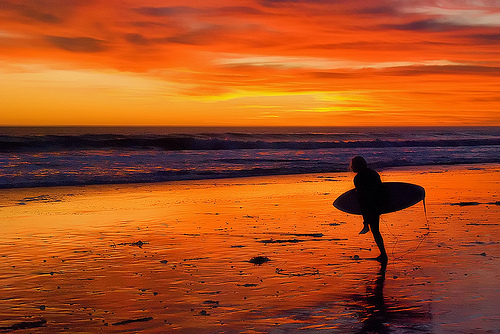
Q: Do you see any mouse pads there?
A: No, there are no mouse pads.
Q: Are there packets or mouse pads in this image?
A: No, there are no mouse pads or packets.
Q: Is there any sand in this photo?
A: Yes, there is sand.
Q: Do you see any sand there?
A: Yes, there is sand.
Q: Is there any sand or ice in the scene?
A: Yes, there is sand.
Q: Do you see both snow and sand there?
A: No, there is sand but no snow.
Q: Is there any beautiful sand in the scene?
A: Yes, there is beautiful sand.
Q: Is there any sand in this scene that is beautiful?
A: Yes, there is sand that is beautiful.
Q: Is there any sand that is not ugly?
A: Yes, there is beautiful sand.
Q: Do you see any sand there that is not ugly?
A: Yes, there is beautiful sand.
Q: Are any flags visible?
A: No, there are no flags.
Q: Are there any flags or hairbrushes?
A: No, there are no flags or hairbrushes.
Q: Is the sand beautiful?
A: Yes, the sand is beautiful.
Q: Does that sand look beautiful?
A: Yes, the sand is beautiful.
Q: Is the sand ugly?
A: No, the sand is beautiful.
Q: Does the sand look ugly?
A: No, the sand is beautiful.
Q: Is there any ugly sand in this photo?
A: No, there is sand but it is beautiful.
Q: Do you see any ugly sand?
A: No, there is sand but it is beautiful.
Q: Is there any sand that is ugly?
A: No, there is sand but it is beautiful.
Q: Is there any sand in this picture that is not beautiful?
A: No, there is sand but it is beautiful.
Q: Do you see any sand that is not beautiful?
A: No, there is sand but it is beautiful.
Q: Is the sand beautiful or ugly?
A: The sand is beautiful.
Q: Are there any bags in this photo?
A: No, there are no bags.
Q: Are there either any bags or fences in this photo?
A: No, there are no bags or fences.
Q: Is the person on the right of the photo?
A: Yes, the person is on the right of the image.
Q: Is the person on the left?
A: No, the person is on the right of the image.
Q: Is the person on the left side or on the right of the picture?
A: The person is on the right of the image.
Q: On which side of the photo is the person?
A: The person is on the right of the image.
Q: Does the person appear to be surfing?
A: Yes, the person is surfing.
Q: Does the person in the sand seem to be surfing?
A: Yes, the person is surfing.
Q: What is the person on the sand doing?
A: The person is surfing.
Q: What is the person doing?
A: The person is surfing.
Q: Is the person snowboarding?
A: No, the person is surfing.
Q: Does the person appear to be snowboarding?
A: No, the person is surfing.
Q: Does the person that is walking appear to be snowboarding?
A: No, the person is surfing.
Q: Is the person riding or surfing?
A: The person is surfing.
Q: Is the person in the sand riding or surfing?
A: The person is surfing.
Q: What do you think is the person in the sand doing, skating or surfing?
A: The person is surfing.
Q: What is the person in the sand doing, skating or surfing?
A: The person is surfing.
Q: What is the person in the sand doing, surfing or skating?
A: The person is surfing.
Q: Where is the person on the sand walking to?
A: The person is walking to the water.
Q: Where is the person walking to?
A: The person is walking to the water.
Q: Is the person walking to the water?
A: Yes, the person is walking to the water.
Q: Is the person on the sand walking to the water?
A: Yes, the person is walking to the water.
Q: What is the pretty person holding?
A: The person is holding the surfboard.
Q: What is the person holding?
A: The person is holding the surfboard.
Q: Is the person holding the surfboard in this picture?
A: Yes, the person is holding the surfboard.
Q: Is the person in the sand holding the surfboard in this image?
A: Yes, the person is holding the surfboard.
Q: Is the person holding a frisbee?
A: No, the person is holding the surfboard.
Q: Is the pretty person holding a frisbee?
A: No, the person is holding the surfboard.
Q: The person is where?
A: The person is in the sand.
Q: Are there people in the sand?
A: Yes, there is a person in the sand.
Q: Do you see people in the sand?
A: Yes, there is a person in the sand.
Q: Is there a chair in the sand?
A: No, there is a person in the sand.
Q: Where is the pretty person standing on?
A: The person is standing on the sand.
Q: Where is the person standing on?
A: The person is standing on the sand.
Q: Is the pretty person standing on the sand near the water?
A: Yes, the person is standing on the sand.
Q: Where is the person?
A: The person is on the sand.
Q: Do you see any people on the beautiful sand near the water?
A: Yes, there is a person on the sand.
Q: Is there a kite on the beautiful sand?
A: No, there is a person on the sand.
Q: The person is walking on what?
A: The person is walking on the sand.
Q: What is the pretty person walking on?
A: The person is walking on the sand.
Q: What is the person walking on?
A: The person is walking on the sand.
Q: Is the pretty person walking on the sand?
A: Yes, the person is walking on the sand.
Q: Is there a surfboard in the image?
A: Yes, there is a surfboard.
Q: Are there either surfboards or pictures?
A: Yes, there is a surfboard.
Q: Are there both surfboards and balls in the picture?
A: No, there is a surfboard but no balls.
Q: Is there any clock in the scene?
A: No, there are no clocks.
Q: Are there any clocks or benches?
A: No, there are no clocks or benches.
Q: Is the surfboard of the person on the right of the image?
A: Yes, the surfboard is on the right of the image.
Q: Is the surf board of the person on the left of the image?
A: No, the surfboard is on the right of the image.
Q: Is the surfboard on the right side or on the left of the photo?
A: The surfboard is on the right of the image.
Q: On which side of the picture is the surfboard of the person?
A: The surf board is on the right of the image.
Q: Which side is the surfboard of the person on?
A: The surf board is on the right of the image.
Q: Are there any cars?
A: No, there are no cars.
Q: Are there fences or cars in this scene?
A: No, there are no cars or fences.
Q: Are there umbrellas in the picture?
A: No, there are no umbrellas.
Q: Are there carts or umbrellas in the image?
A: No, there are no umbrellas or carts.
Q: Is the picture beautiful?
A: Yes, the picture is beautiful.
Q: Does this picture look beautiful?
A: Yes, the picture is beautiful.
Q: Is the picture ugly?
A: No, the picture is beautiful.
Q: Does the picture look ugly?
A: No, the picture is beautiful.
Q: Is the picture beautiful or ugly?
A: The picture is beautiful.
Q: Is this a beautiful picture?
A: Yes, this is a beautiful picture.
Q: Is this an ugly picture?
A: No, this is a beautiful picture.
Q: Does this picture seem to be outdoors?
A: Yes, the picture is outdoors.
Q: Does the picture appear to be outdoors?
A: Yes, the picture is outdoors.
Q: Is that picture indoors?
A: No, the picture is outdoors.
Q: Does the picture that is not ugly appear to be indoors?
A: No, the picture is outdoors.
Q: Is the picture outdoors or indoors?
A: The picture is outdoors.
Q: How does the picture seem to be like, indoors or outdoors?
A: The picture is outdoors.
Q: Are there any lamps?
A: No, there are no lamps.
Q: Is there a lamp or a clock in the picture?
A: No, there are no lamps or clocks.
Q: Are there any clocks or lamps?
A: No, there are no lamps or clocks.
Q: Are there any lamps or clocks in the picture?
A: No, there are no lamps or clocks.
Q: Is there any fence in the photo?
A: No, there are no fences.